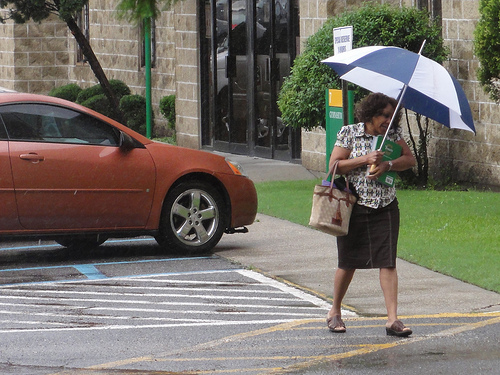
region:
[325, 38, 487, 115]
black and white open umbrella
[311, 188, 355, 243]
purse of woman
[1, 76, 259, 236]
red car in lot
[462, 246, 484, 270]
short green and yellow grass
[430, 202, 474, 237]
short green and yellow grass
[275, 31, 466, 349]
A woman carrying an umbrella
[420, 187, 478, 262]
Grass in the photo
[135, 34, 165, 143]
A metallic pole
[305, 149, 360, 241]
A handbag in the hand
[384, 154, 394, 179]
A wrist watch on the hand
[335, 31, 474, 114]
A blue and white umbrella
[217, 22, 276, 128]
A door on the building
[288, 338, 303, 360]
Redraw Box Back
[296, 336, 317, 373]
Redraw Box Back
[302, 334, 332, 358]
Redraw Box Back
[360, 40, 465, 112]
blue and white umbrella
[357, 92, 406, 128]
woman has curly hair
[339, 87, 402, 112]
woman has brown hair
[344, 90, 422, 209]
white and gold shirt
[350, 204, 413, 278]
woman has brown dress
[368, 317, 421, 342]
woman has brown shoes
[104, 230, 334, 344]
white lines in lot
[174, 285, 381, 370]
yellow lines in lot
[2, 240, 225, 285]
blue lines in lot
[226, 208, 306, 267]
sidewalk is light brown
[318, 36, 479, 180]
an umbrella with blue and white stripes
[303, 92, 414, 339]
a woman carrying books and a bag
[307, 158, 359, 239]
a bag with brown straps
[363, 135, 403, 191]
a green text book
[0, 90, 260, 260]
an orange car parked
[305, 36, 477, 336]
a woman with an umbrella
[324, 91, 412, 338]
a woman with curly hair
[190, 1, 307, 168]
a buildings large black door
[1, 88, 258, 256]
an orange compact car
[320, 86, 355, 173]
a green and yellow sign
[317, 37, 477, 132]
an open blue and white striped umbrella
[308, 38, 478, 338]
a woman walking under umbrella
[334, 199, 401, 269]
a woman's brown skirt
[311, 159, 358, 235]
a woman's brown purse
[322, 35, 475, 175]
the umbrella is blue and white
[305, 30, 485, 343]
A woman holding an umbrella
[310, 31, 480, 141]
A blue and white umbrella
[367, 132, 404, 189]
A closed green book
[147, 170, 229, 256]
A black rubber tire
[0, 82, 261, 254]
The side of an orange car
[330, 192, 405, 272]
A brown colored skirt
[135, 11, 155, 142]
A thin green pole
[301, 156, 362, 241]
A brown and tan purse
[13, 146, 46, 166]
Handle of a car door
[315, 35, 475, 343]
A woman holding an umbrella.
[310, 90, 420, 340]
A woman wearing a skirt, blouse and sandals.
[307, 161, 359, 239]
A brown handbag.